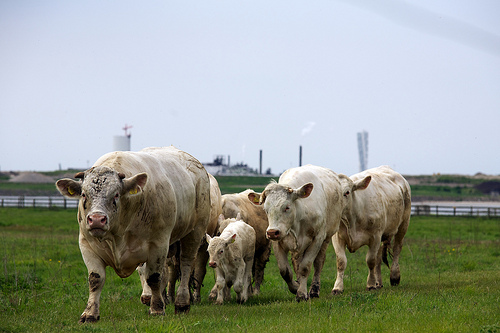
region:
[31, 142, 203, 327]
First cow in line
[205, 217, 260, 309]
Second cow in line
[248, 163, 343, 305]
Third cow in line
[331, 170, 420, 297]
Cow behind third cow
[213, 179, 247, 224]
Cow behind first cow in line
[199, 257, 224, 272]
Cows nose is pink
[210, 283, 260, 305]
Baby cow front feet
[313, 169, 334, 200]
Cows fur is white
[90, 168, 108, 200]
Black spot on cows head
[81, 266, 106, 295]
Black spot on cows leg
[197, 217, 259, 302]
a baby cow walking with bigger cows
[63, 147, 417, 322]
a herd of cows walking in line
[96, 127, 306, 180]
a building in the background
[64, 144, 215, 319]
the biggest cow in front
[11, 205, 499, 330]
a field of grass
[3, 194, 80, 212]
some of the wooden fence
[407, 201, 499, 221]
the other part of the thread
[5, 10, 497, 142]
the blue sky above everything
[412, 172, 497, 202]
some more grass off in the back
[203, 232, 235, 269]
the cute face of the baby cow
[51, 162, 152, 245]
the head of a cow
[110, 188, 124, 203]
the eye of a cow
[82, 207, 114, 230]
the nose of a cow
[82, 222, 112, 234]
the mouth of a cow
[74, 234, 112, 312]
the leg of a cow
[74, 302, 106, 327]
the hoof of a cow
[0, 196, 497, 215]
a fence around the field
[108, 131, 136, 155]
a white silo behind the field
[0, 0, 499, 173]
a gray sky overhead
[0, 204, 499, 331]
a green grassy field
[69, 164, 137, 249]
This cow has a rather large face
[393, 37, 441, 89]
There is a light blue sky in the distance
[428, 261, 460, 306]
There is green grass in the foreground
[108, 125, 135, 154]
There is a feed tower on the farm in the distance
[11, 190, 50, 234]
There is a fence that is in the distance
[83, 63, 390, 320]
This photo was taken in the city of Cashton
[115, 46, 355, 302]
This photo was taken in the state of Wisconsin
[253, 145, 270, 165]
There is a steel tower in the distance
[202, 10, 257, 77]
The weather looks slightly overcast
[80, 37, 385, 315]
This entire photograph was taken by Jackson Mingus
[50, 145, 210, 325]
a large white cow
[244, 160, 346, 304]
a large white cow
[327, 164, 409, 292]
a large white cow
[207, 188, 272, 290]
a large white cow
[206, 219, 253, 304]
a small baby calf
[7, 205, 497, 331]
a patch of green grass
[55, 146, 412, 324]
a small herd of cows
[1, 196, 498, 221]
a long wooden fence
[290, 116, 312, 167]
tall smoke stack in distance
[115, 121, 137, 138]
tall red crane in distance